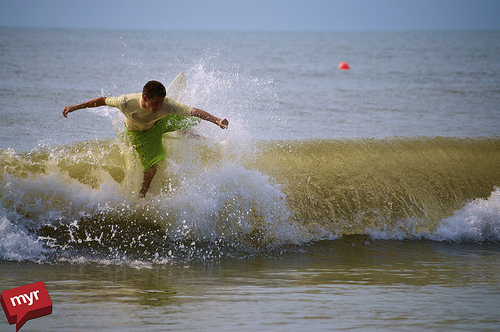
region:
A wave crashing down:
[0, 133, 499, 265]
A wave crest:
[269, 135, 449, 237]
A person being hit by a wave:
[61, 80, 230, 198]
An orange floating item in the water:
[338, 58, 350, 70]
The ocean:
[1, 28, 498, 330]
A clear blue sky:
[0, 0, 495, 30]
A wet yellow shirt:
[103, 90, 193, 132]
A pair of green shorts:
[125, 117, 199, 169]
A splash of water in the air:
[170, 49, 279, 136]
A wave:
[3, 135, 493, 259]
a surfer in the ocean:
[46, 60, 241, 219]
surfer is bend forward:
[51, 60, 250, 214]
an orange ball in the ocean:
[330, 48, 360, 80]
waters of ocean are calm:
[8, 22, 498, 101]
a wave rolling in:
[9, 133, 499, 264]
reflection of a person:
[80, 262, 221, 320]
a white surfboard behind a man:
[145, 60, 204, 108]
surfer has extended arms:
[53, 73, 247, 203]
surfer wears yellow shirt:
[53, 78, 241, 203]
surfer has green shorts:
[56, 77, 245, 212]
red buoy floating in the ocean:
[332, 58, 357, 78]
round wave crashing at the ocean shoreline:
[226, 131, 482, 248]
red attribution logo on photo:
[0, 276, 56, 330]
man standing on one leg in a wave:
[61, 74, 233, 219]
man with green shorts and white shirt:
[61, 78, 236, 241]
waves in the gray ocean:
[379, 27, 487, 119]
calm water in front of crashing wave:
[229, 259, 461, 319]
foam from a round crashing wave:
[164, 169, 311, 259]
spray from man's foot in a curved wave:
[168, 56, 297, 140]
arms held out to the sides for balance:
[45, 69, 240, 151]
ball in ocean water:
[323, 50, 365, 82]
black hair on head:
[144, 79, 162, 94]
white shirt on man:
[121, 101, 138, 116]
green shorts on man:
[143, 141, 155, 156]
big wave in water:
[258, 150, 382, 219]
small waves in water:
[279, 287, 388, 329]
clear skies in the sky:
[242, 4, 465, 31]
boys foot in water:
[176, 126, 204, 140]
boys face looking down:
[122, 79, 178, 122]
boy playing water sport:
[56, 71, 266, 228]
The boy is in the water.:
[33, 32, 282, 237]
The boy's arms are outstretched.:
[61, 55, 236, 160]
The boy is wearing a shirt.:
[51, 68, 244, 225]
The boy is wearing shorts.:
[61, 73, 245, 230]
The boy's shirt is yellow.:
[61, 68, 245, 228]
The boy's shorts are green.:
[53, 78, 244, 225]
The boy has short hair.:
[56, 58, 241, 214]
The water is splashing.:
[1, 35, 498, 277]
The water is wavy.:
[0, 24, 499, 329]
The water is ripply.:
[1, 27, 497, 329]